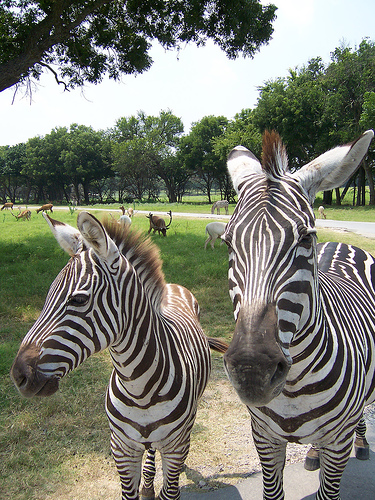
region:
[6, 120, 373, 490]
a group of animals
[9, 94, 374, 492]
a pair of zebras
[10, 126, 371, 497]
stripes on the zebras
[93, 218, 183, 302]
mane on the zebra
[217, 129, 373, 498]
The largest black and white zebra.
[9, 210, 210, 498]
Smaller zebra beside a larger one.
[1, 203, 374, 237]
A grey paved road past the animals.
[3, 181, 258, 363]
animals behind the zebras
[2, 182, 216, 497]
the zebra is striped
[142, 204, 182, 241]
the animal has antlers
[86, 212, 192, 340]
the zebra has a striped mane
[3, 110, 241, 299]
the trees and grass are green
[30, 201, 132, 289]
the zebras ears are sticking up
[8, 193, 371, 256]
a path through the grass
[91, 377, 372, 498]
the zebras have legs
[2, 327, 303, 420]
the zebras have black noses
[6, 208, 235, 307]
the grass is tall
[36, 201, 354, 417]
two zebra faces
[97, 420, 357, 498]
the four front legs of two zebras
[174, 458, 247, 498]
a zebra's shadow on the ground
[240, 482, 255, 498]
a concrete walkway under the zebras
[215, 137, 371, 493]
a zebra looking at the camera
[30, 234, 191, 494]
a young zebra looking to the left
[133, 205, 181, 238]
a deer with very large antlers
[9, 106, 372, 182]
a long line of green trees along the road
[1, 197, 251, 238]
deer zebras and ostriches in the background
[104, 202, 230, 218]
a concrete roadway between several animals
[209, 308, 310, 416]
A black zebra's snout.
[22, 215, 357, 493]
One large and one small zebra.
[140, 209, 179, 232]
Extremely large antlers on an animal.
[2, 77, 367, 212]
Large grove of green leafy trees.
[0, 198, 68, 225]
Three animals grazing on the grass.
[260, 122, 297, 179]
A tuft of hair growing between a zebra's ears.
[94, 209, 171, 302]
The mane of a small zebra.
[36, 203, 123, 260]
Two zebra ears.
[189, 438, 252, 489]
Pebbles by the side of a road.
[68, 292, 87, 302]
The eyelashes of a small zebra.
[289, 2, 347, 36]
The sky is cloudy.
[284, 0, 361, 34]
The sky is bright.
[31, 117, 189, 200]
Trees are is the background.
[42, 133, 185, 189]
The trees are green.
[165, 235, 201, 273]
The grass is green.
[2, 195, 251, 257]
Other animals are in the background.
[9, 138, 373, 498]
Two zebras are facing the camera.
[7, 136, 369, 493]
The zebras are black and white.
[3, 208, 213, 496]
The zebra on the left is smaller.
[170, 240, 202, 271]
The grass is tall.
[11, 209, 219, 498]
a young zebra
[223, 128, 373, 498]
an adult sized zebra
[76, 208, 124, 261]
a young zebra's left ear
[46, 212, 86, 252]
a young zebra's right ear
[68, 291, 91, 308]
a young zebra's left eye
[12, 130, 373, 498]
a young zebra standing with an adult zebra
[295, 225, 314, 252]
and adult zebra's left eye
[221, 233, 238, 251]
and adult zebra's right eye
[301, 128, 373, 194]
and adult zebra's left ear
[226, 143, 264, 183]
and adult zebra's right ear